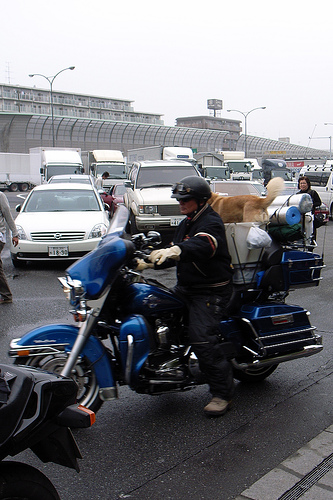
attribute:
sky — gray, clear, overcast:
[177, 17, 256, 77]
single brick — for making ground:
[256, 456, 323, 494]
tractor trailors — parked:
[32, 154, 278, 184]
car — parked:
[8, 190, 107, 263]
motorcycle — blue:
[47, 249, 316, 381]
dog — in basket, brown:
[204, 186, 295, 225]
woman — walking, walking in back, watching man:
[293, 177, 326, 224]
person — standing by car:
[99, 174, 111, 210]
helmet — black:
[172, 177, 211, 211]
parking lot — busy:
[176, 449, 221, 498]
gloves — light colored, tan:
[150, 243, 180, 264]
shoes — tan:
[202, 393, 248, 429]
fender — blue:
[17, 325, 117, 384]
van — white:
[126, 169, 214, 235]